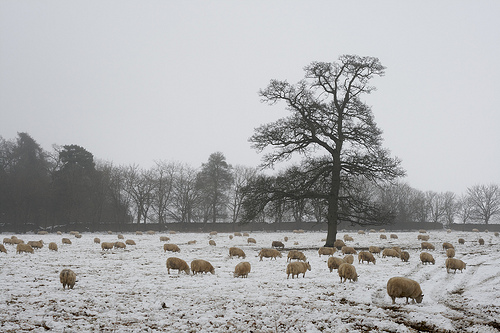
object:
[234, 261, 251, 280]
sheep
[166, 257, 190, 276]
sheep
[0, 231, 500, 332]
snow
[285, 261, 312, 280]
sheep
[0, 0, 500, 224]
sky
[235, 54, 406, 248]
tree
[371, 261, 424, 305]
track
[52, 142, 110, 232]
tree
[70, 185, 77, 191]
needles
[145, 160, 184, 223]
tree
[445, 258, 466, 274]
sheep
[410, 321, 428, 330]
dirt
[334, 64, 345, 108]
branch